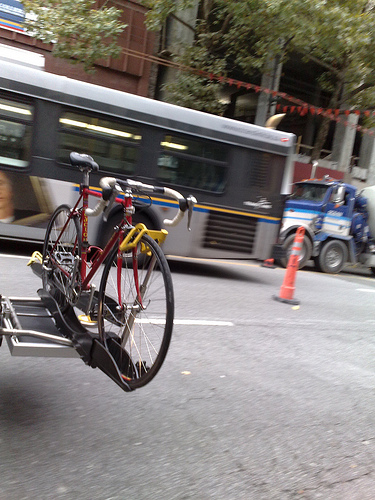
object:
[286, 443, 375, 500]
cracks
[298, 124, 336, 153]
ground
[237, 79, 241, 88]
flag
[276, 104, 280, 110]
flag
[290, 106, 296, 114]
flag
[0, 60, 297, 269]
bus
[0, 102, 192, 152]
yellow light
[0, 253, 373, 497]
pavement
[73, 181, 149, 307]
frame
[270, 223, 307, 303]
cone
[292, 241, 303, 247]
stripe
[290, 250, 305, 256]
stripe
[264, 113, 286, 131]
exhaust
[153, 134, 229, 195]
windows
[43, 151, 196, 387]
bicycle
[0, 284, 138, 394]
bike rack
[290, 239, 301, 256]
white part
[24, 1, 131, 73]
tree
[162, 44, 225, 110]
tree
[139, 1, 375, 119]
tree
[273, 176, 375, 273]
cab